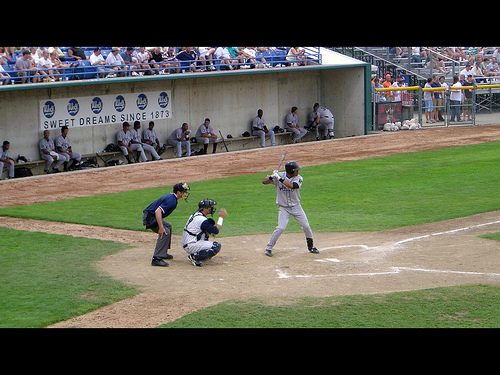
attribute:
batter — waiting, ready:
[262, 159, 321, 259]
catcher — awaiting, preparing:
[180, 197, 228, 270]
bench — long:
[3, 122, 335, 178]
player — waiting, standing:
[310, 101, 337, 142]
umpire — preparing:
[141, 179, 191, 271]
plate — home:
[311, 253, 346, 269]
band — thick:
[214, 212, 226, 229]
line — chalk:
[269, 265, 399, 280]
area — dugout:
[0, 63, 367, 183]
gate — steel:
[417, 84, 476, 128]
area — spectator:
[1, 45, 323, 84]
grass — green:
[1, 145, 499, 329]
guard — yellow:
[372, 80, 499, 91]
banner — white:
[37, 88, 177, 132]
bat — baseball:
[269, 150, 288, 180]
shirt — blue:
[143, 193, 179, 227]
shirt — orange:
[381, 79, 396, 99]